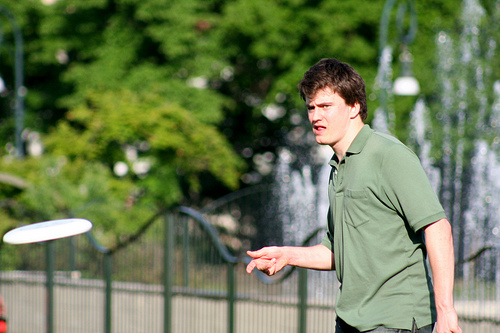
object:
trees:
[0, 4, 500, 273]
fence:
[0, 172, 500, 333]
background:
[0, 0, 500, 333]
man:
[244, 58, 461, 333]